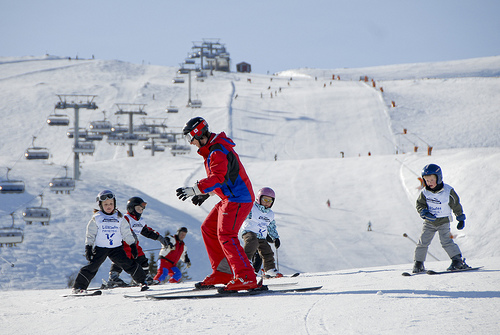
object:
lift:
[111, 100, 149, 157]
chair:
[44, 110, 74, 128]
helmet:
[181, 114, 209, 142]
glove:
[173, 183, 196, 200]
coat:
[195, 133, 254, 205]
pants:
[198, 195, 258, 282]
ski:
[145, 284, 325, 303]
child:
[409, 163, 474, 274]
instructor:
[175, 116, 261, 292]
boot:
[218, 275, 268, 290]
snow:
[254, 297, 346, 317]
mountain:
[84, 57, 384, 148]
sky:
[258, 13, 372, 66]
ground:
[265, 108, 328, 166]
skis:
[123, 281, 300, 298]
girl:
[241, 186, 283, 277]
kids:
[72, 188, 150, 296]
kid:
[105, 196, 165, 287]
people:
[152, 225, 190, 283]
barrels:
[412, 146, 419, 153]